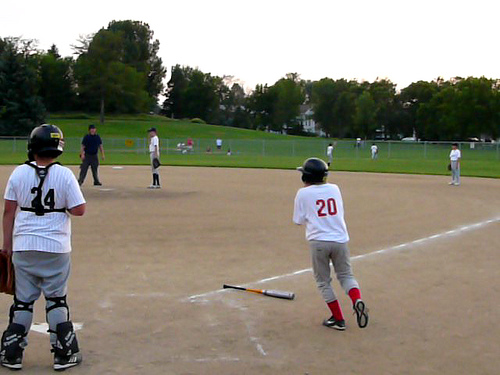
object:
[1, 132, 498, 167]
fence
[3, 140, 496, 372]
baseball field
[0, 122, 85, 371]
boy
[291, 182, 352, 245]
jersey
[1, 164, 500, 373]
clay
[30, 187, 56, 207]
24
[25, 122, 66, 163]
helmet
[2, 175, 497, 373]
dirt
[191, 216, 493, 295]
lines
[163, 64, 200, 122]
trees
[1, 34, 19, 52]
leaves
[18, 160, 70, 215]
chest mask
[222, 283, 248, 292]
handle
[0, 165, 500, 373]
ground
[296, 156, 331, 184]
helmet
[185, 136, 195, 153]
person sitting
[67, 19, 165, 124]
tree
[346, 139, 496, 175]
grass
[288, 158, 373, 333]
baseball player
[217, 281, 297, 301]
bat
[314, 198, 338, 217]
20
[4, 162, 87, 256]
shirt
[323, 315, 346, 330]
sneaker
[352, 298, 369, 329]
sneaker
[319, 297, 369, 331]
pair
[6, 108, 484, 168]
park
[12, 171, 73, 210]
chest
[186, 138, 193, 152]
person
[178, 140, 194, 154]
chair